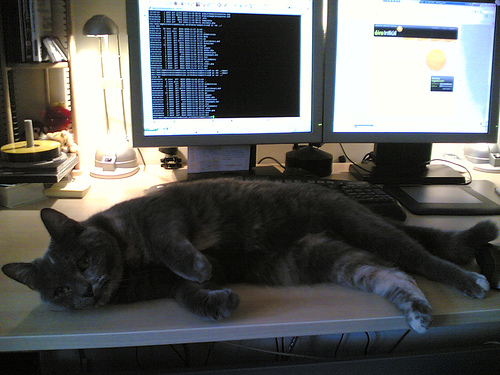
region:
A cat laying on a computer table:
[2, 170, 498, 334]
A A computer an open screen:
[326, 0, 498, 146]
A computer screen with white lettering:
[127, 0, 322, 146]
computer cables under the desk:
[263, 332, 423, 362]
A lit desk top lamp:
[72, 11, 140, 181]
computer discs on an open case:
[2, 116, 62, 174]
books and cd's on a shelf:
[3, 2, 74, 68]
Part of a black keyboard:
[339, 175, 406, 214]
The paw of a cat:
[398, 284, 438, 338]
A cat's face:
[0, 198, 129, 318]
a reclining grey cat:
[2, 176, 492, 336]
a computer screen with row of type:
[125, 0, 323, 147]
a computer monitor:
[323, 0, 498, 182]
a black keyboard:
[185, 173, 405, 223]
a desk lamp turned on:
[80, 12, 140, 179]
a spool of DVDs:
[0, 118, 65, 167]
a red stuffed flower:
[37, 100, 70, 132]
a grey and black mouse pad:
[380, 181, 499, 214]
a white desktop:
[1, 142, 498, 352]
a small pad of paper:
[45, 179, 91, 199]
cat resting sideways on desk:
[3, 174, 493, 336]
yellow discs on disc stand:
[4, 119, 69, 180]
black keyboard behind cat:
[177, 163, 402, 223]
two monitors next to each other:
[119, 0, 499, 145]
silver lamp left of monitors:
[77, 12, 143, 182]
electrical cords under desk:
[87, 326, 498, 373]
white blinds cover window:
[2, 1, 77, 146]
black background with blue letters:
[147, 4, 307, 133]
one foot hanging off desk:
[402, 299, 431, 336]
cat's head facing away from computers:
[21, 222, 121, 310]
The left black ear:
[26, 197, 83, 246]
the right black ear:
[0, 257, 41, 294]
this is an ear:
[26, 195, 98, 250]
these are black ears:
[1, 186, 74, 296]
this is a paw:
[174, 251, 222, 290]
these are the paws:
[181, 248, 254, 320]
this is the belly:
[206, 228, 255, 280]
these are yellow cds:
[0, 125, 75, 164]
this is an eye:
[68, 247, 96, 279]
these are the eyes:
[46, 245, 108, 302]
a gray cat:
[1, 176, 495, 329]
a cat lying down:
[1, 174, 499, 334]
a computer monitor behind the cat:
[128, 0, 320, 179]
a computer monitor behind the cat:
[327, 0, 488, 178]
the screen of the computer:
[140, 1, 306, 131]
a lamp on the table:
[81, 18, 140, 170]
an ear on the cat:
[38, 206, 84, 236]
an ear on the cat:
[0, 261, 42, 290]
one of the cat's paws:
[157, 242, 217, 279]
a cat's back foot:
[388, 286, 437, 337]